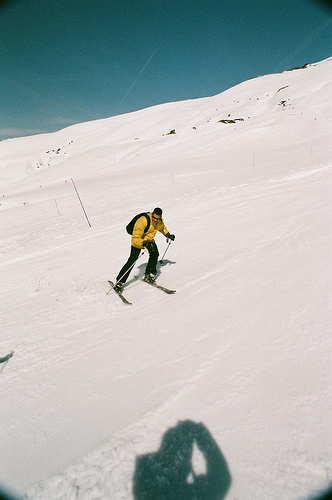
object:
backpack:
[124, 211, 151, 238]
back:
[132, 212, 150, 232]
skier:
[111, 201, 179, 295]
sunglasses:
[151, 214, 161, 222]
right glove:
[143, 239, 154, 252]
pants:
[116, 238, 160, 283]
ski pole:
[159, 239, 173, 266]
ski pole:
[105, 247, 147, 296]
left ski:
[141, 274, 176, 295]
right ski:
[108, 279, 134, 307]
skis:
[105, 274, 136, 307]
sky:
[0, 2, 330, 143]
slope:
[0, 55, 331, 498]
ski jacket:
[132, 210, 170, 251]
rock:
[218, 117, 228, 125]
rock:
[165, 127, 177, 137]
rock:
[234, 113, 245, 122]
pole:
[69, 177, 93, 228]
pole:
[51, 199, 62, 218]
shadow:
[127, 410, 232, 500]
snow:
[0, 56, 331, 499]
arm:
[131, 218, 154, 254]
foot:
[112, 280, 125, 296]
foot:
[143, 271, 156, 284]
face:
[151, 212, 161, 225]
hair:
[153, 207, 163, 217]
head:
[151, 207, 163, 223]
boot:
[113, 277, 124, 293]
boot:
[143, 270, 157, 283]